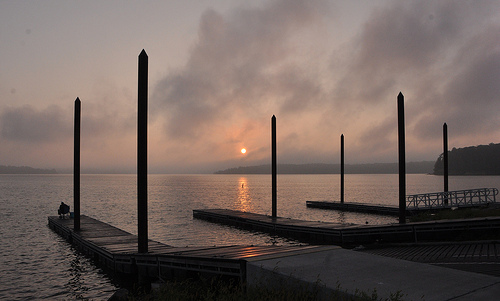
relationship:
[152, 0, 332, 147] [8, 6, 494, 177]
clouds in sky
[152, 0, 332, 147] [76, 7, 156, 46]
clouds in sky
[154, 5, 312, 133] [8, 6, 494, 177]
clouds in sky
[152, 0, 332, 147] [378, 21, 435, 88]
clouds in blue sky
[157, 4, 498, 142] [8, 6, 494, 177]
clouds in sky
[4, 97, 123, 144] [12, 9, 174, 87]
cloud in sky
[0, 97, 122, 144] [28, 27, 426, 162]
cloud in sky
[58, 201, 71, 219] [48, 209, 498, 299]
person sitting on dock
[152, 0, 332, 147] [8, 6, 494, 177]
clouds over sky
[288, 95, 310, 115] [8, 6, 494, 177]
clouds over sky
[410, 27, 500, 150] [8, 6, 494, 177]
clouds over sky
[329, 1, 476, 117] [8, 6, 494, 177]
clouds over sky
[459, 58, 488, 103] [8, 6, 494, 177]
clouds over sky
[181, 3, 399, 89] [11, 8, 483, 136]
clouds in sky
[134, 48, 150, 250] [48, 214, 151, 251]
pole on dock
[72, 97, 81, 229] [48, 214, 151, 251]
wood post on dock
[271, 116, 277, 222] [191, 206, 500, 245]
wood post on boat dock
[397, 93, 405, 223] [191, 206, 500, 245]
wood post on boat dock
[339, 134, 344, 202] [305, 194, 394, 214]
wood post on dock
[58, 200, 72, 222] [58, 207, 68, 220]
person sitting in chair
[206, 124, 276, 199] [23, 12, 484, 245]
sun setting in sky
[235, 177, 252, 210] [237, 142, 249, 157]
sun reflection of sun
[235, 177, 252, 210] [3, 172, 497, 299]
sun reflection on water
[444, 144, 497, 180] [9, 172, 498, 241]
trees next to water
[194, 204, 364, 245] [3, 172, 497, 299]
boat dock on water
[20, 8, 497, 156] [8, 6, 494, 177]
clouds in sky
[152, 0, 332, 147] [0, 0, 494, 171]
clouds in blue sky